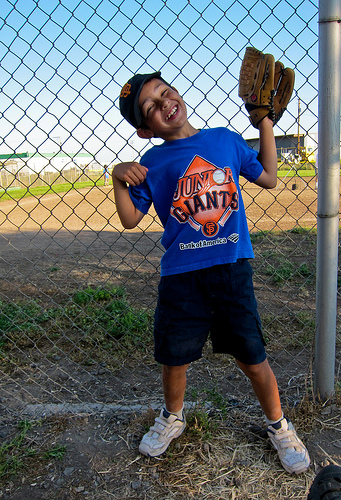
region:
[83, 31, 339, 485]
a boy with a baseball glove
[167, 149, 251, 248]
orange diamond on shirt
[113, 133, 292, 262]
a blue and orange shirt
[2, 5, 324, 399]
chain link fence behind boy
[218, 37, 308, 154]
baseball glove on hand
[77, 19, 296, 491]
a boy ready to play baseball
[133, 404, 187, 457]
this is a shoe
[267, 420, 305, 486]
this is a shoe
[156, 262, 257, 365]
these are blue shorts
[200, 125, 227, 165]
this is a blue t shirt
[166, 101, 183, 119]
this is a mouth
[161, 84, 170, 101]
this is an eye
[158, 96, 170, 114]
this is a nose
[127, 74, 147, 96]
this is a black cap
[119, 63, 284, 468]
this is a boy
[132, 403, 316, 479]
Pair of white sneakers with velcro straps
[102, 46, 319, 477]
A young boy wearing black shorts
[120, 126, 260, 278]
Blue t-shirt with orange logo on the front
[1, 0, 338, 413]
Chain link fence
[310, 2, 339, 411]
Pole to hold up fencing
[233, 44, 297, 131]
Baseball glove on left hand of a boy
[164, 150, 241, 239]
Junior Giant's logo on front of a t-shirt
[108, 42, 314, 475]
A boy wearing white sneakers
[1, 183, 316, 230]
White lines of a baseball diamond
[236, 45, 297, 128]
A brown baseball glove.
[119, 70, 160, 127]
A black hat on a boy's head.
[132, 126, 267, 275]
A blue shirt being worn.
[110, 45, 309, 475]
A kid with a baseball glove smiling.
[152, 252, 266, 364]
A dark blue pair of shorts on a boy.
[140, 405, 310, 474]
A pair of white sneakers on a boy.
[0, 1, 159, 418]
A steel, wire fence.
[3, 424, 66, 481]
A patch of grass in the dirt.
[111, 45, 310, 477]
A boy standing in front of a wire fence.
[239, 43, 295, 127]
A light brown baseball glove.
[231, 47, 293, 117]
boy has a mitt on his left hand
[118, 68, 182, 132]
boy has on a ball cap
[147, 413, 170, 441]
sneakers have velcro straps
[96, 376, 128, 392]
A diamond in the fence.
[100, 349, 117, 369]
A diamond in the fence.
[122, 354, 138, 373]
A diamond in the fence.